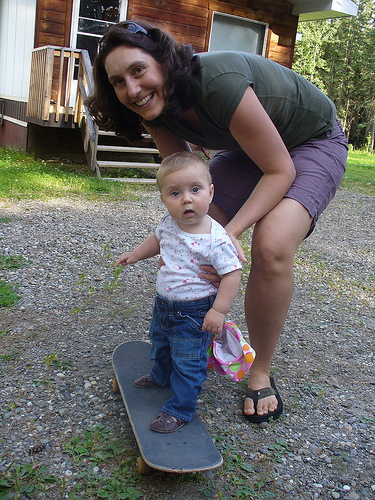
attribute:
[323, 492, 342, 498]
pebble — small, grey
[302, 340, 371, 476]
pebble — grey, small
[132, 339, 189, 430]
skateboard — grey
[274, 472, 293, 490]
pebble — small